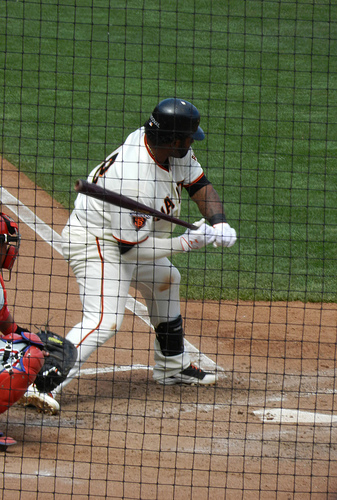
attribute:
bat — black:
[78, 180, 192, 235]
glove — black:
[32, 333, 79, 387]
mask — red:
[0, 213, 24, 273]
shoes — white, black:
[26, 364, 224, 410]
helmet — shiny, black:
[148, 97, 210, 138]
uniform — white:
[65, 150, 210, 353]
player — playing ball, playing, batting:
[41, 103, 255, 371]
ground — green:
[234, 62, 333, 244]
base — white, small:
[256, 404, 334, 440]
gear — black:
[153, 321, 196, 354]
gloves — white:
[191, 219, 242, 249]